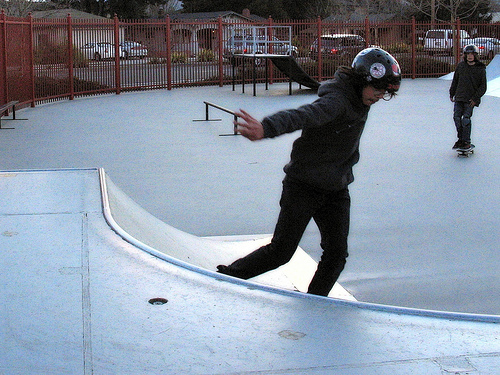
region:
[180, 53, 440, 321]
a skate board park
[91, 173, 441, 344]
a side ramp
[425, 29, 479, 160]
a boy on a skate board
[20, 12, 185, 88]
a red fence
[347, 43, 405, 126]
a black skate board helmet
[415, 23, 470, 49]
a white van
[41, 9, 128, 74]
a tan house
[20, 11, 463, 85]
a suburban street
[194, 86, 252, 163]
a red rail bar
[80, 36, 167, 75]
two sedans parked in a driveway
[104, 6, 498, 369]
two people at a skate park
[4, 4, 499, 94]
a maroon iron fence around park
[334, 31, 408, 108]
kid wearing a black helmet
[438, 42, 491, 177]
young boy on skateboard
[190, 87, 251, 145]
a grinding rail at skate park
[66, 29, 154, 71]
two cars parked in front of a garage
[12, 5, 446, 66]
row of houses across the street from park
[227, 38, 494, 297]
two boys wearing all dark colors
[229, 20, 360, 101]
a lifted ramp for doing tricks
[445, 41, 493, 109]
boy wearing a long sleeve shirt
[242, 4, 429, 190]
the guy in black helmet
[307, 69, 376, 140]
the guy in black helmet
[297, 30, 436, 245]
the guy in black helmet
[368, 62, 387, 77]
White sticker on a helmet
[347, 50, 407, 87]
Black helmet on a boy's head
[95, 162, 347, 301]
Ramp at a skate park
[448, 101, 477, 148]
Boy wearing black jeans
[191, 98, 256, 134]
Rail in a skate park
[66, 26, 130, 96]
Red fence around a skate park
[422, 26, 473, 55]
White truck on a street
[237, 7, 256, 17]
Brick chimney on a house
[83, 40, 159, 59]
Two cars parked in a driveway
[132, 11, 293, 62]
House behind a skatepark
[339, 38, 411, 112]
teen with black helmet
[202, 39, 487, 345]
teen stake boarding down a slope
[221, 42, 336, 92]
skate boarding wooden frame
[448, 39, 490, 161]
teenage with stake board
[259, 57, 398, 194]
teen with gray hoodie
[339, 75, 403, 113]
boy with reading glasses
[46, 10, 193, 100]
tall red iron fence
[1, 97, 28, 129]
wood and iron bench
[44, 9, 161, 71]
two white cars parked in front of a garage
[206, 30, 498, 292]
two teens stake boarding in dark clothes